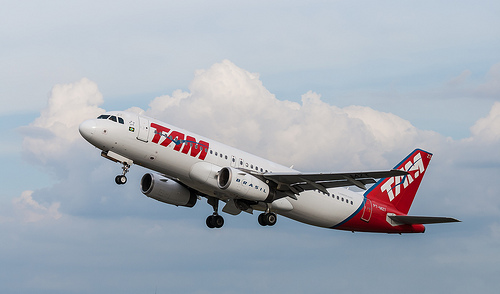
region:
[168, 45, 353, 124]
puffy white clouds in the sky above the plane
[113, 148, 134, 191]
landing gear down on the plane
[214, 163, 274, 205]
engine on the right side of the plane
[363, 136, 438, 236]
red tail wing with right letters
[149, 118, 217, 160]
large red letters on the plane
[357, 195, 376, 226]
back door on the airplane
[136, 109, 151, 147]
front door on the airplane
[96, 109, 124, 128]
cockpit windows on the front of the plane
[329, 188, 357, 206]
row of windows at back of plane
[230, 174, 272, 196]
letters painted on side of engine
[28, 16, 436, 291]
picture taken outdoors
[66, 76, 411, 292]
picture taken during the day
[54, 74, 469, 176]
stormy clouds behind plane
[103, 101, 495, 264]
the plane is flying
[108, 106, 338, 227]
the plane has a white body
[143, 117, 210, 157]
the plane says TAM on it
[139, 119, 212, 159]
the TAM is in red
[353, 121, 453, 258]
the tail of the plane is red and white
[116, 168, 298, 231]
the wheels on the plane are down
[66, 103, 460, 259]
the plane is at an angle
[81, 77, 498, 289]
a plane in the sky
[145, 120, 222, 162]
the logo is red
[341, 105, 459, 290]
the plane has tail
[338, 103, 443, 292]
plane's tail is red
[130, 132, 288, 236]
the engines are white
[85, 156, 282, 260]
the plane has wheels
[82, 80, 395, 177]
the sky is cloudy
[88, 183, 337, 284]
the tires are black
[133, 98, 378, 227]
the plane is white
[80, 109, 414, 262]
airplane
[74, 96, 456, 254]
red and white airplane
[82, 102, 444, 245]
flying red and white airplane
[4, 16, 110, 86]
white clouds against blue sky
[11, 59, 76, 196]
white clouds against blue sky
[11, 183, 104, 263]
white clouds against blue sky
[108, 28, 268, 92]
white clouds against blue sky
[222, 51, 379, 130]
white clouds against blue sky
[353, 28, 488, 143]
white clouds against blue sky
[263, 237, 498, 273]
white clouds against blue sky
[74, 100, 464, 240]
a white and red plane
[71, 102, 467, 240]
a plane is flying in the sky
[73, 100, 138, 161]
the cockpit of a plane has windows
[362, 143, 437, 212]
vertical stabilizer of plane is red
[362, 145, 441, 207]
vertical stabilizer has blue border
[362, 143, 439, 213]
white letters on vertical stabilizer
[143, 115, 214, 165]
red letters on plane says "TAM"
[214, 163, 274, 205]
an engine on right side of plane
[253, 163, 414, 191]
a wing behind an engine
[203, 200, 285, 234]
back wheels of plane